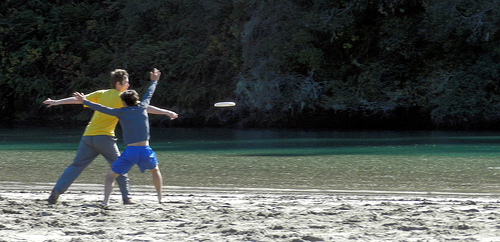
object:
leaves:
[416, 70, 500, 122]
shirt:
[82, 89, 128, 137]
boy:
[45, 69, 179, 206]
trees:
[0, 0, 499, 126]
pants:
[48, 136, 129, 198]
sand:
[0, 192, 500, 242]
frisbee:
[214, 101, 236, 107]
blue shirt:
[84, 80, 156, 145]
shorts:
[111, 145, 158, 176]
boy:
[70, 67, 180, 210]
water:
[0, 135, 500, 192]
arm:
[141, 80, 155, 109]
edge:
[0, 125, 500, 149]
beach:
[0, 193, 500, 242]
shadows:
[245, 140, 490, 161]